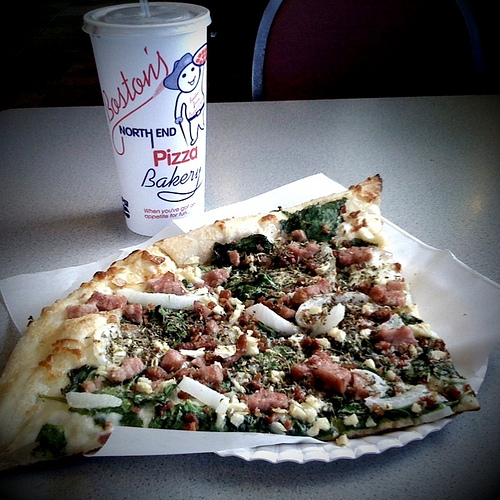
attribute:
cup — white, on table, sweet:
[78, 11, 227, 229]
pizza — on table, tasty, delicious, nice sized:
[28, 138, 414, 400]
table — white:
[203, 78, 495, 173]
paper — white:
[278, 167, 355, 204]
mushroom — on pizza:
[212, 224, 272, 256]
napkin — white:
[101, 415, 187, 463]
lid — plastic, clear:
[51, 1, 222, 46]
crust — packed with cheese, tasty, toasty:
[25, 214, 227, 351]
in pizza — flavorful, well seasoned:
[140, 161, 431, 414]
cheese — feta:
[221, 352, 266, 394]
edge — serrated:
[396, 214, 473, 286]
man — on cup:
[153, 51, 258, 149]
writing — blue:
[108, 121, 185, 149]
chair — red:
[251, 3, 491, 166]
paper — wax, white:
[112, 414, 262, 461]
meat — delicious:
[289, 326, 449, 397]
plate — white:
[0, 190, 449, 293]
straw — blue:
[124, 0, 159, 27]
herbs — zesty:
[215, 225, 283, 304]